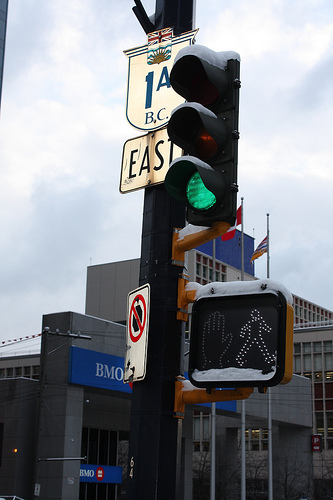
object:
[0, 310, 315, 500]
bank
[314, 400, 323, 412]
windows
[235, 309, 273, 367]
image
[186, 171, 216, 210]
light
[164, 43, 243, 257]
sign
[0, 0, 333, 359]
sky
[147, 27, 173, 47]
flag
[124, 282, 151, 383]
sign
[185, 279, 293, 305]
snow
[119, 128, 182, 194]
direction sign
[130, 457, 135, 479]
number 64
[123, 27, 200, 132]
roadway sign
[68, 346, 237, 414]
business sign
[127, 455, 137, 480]
white number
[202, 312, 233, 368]
hand outline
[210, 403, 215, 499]
grey pole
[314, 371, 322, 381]
window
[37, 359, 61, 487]
grey wall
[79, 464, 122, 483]
blue sign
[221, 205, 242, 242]
flag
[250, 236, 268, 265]
flag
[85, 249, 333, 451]
building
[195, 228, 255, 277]
accent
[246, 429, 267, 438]
lights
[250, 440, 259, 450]
windows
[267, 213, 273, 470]
pole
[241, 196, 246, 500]
pole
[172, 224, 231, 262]
arm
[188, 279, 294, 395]
cross sign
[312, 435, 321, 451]
parking sign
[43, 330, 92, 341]
rod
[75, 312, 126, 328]
snow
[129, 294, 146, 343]
cross out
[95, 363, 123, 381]
letters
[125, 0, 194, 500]
light post